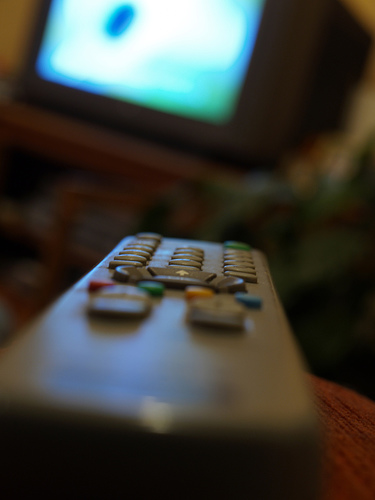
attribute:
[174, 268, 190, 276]
arrow — small , white 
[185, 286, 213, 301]
button — yellow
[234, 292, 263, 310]
button — red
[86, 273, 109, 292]
button — red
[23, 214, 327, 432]
remote — grey , long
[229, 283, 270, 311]
button — blue 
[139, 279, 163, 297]
button — green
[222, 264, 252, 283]
button — gray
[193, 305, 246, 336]
button — grey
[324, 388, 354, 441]
table — brown 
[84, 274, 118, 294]
button — red 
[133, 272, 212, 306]
button — gray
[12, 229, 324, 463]
remote control — gray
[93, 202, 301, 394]
remote — television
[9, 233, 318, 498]
remote — television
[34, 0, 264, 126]
screen — glowing, blue 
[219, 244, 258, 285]
buttons — grey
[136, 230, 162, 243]
button — grey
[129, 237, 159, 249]
button — grey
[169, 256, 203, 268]
button — grey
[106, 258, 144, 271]
button — grey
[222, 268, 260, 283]
button — grey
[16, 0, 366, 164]
screen — out of focus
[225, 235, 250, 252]
button — small , green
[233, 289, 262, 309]
button — blue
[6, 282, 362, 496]
surface — brown